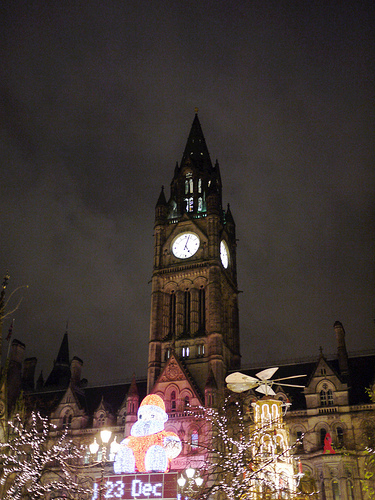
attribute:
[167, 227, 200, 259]
clock — white and black